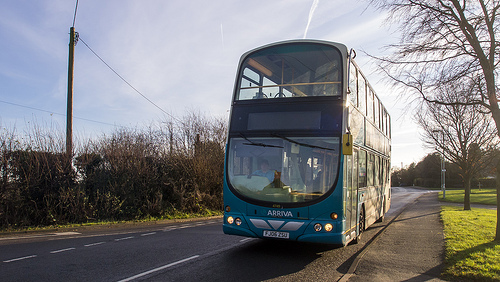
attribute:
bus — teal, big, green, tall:
[224, 41, 393, 249]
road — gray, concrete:
[1, 185, 438, 280]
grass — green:
[440, 189, 499, 281]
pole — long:
[66, 27, 74, 164]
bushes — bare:
[0, 108, 228, 228]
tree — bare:
[357, 1, 500, 139]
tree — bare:
[415, 79, 500, 209]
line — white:
[117, 255, 201, 281]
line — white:
[86, 242, 105, 248]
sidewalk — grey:
[340, 191, 446, 281]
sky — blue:
[0, 1, 499, 182]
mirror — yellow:
[343, 134, 353, 156]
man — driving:
[251, 161, 276, 182]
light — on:
[325, 224, 333, 231]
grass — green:
[439, 189, 500, 206]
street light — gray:
[433, 129, 446, 189]